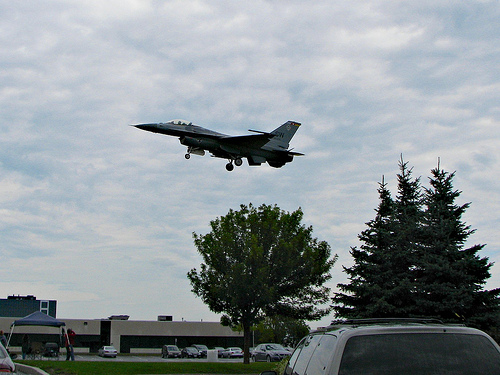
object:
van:
[279, 317, 499, 375]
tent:
[5, 311, 74, 362]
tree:
[182, 201, 330, 363]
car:
[94, 346, 119, 359]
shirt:
[60, 333, 74, 346]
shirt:
[30, 346, 44, 357]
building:
[0, 293, 244, 363]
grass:
[48, 360, 278, 375]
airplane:
[130, 119, 308, 173]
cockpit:
[170, 118, 193, 126]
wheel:
[225, 163, 235, 172]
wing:
[222, 129, 276, 156]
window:
[333, 330, 497, 374]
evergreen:
[184, 159, 499, 323]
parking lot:
[15, 325, 320, 373]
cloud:
[196, 12, 260, 59]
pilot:
[177, 121, 182, 125]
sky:
[0, 0, 499, 118]